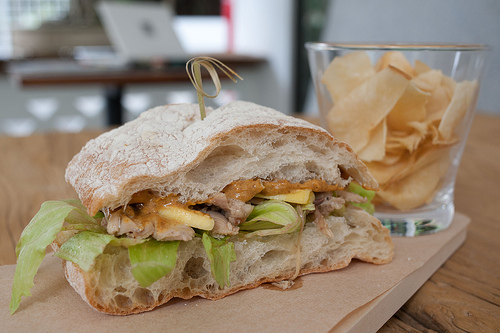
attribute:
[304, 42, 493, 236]
glass — clear, small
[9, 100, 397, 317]
sandwich — cut, small, narrow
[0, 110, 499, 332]
table — brown, wooden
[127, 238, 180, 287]
lettuce — green, curling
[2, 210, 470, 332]
paper — brown, tan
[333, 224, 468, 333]
board — wood, tan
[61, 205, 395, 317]
bread — cut, white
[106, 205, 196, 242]
meat — small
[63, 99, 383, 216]
bread — cut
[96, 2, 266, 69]
laptop — distant, open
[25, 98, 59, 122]
light — heart shaped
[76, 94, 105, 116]
light — heart shaped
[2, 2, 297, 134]
wall — white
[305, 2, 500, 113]
wall — white